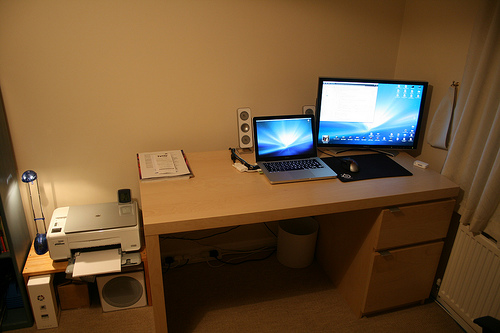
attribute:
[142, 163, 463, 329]
desk — wooden, organized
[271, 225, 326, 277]
can — white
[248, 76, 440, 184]
monitors — on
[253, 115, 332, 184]
laptop — silver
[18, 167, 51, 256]
lamp — on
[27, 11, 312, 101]
wall — tan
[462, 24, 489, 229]
curtains — tan